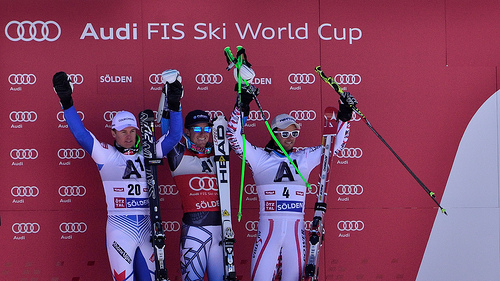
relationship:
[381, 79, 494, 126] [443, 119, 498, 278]
blue tent in back of snow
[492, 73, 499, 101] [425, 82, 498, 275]
tent behind snow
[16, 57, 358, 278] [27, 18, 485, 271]
people against wall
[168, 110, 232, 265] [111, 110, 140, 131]
man has cap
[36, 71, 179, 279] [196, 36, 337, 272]
man holds poles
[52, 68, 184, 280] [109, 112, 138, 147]
man has head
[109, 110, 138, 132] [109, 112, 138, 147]
cap on head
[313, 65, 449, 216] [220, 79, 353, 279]
pole held by person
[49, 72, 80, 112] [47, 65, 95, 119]
gloves on hand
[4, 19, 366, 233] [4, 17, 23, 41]
rings linked to ring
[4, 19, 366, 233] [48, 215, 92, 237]
rings linked to rings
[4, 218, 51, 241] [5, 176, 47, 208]
rings linked to rings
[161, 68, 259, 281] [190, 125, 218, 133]
man wearing shades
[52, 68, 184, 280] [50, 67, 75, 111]
man wearing glove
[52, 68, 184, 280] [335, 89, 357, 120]
man wearing glove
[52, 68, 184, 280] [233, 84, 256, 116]
man wearing glove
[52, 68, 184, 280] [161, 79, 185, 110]
man wearing glove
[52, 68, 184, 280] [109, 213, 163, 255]
man wearing ski sportwear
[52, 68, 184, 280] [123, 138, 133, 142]
man has mouth